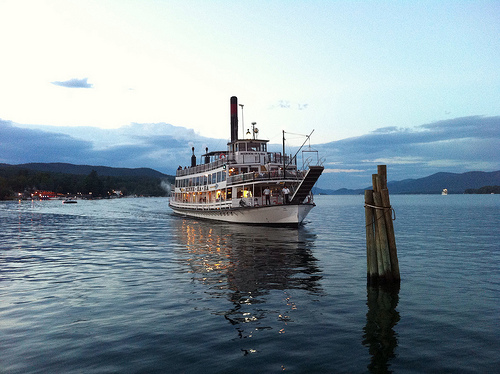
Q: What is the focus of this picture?
A: The Riverboat.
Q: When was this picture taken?
A: Sunset.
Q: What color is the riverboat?
A: White.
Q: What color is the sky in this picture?
A: Blue.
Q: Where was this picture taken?
A: A river.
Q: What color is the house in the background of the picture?
A: Red.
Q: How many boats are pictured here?
A: Two.